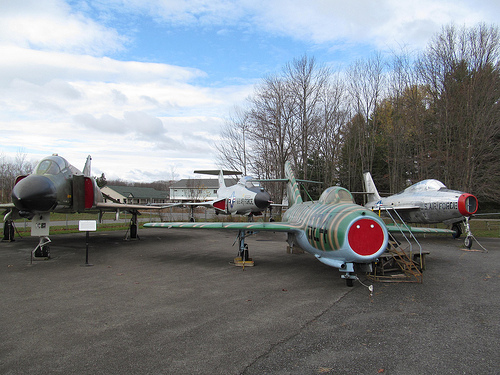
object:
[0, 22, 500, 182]
sky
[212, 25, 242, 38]
clouds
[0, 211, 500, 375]
ground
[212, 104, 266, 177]
trees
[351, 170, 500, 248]
planes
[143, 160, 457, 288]
plane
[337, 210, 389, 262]
front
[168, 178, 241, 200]
buildings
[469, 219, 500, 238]
grass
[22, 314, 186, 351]
concrete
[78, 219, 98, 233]
sign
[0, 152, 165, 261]
plane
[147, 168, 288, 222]
plane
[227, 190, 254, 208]
us air force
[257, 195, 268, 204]
black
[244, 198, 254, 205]
force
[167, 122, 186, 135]
air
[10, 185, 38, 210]
nose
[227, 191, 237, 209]
star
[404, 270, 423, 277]
stairs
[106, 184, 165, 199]
roof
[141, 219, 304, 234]
wing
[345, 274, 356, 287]
wheel